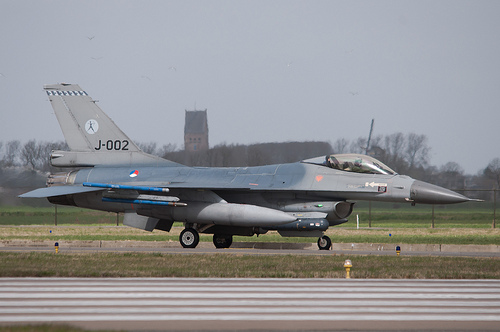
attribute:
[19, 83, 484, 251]
airplane — military, gray, blue, with one seat, small, silver, fighter, jet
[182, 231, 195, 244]
wheel — white, black, back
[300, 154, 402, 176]
cockpit — glass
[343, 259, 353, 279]
marking — yellow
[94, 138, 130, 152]
numbers — identification, identifying, black, j-002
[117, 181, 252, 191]
wing — partial, blue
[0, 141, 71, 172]
trees — without leaves, with no leaves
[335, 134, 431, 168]
trees — without leaves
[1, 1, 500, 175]
sky — overcast, gray, bright grey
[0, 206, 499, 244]
grass — green, in field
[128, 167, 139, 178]
decal — blue, white, red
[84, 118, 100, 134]
decal — with figure, circle, white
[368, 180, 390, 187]
arrow — pointing back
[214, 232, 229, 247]
wheel — black, back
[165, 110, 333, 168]
building — tall, narrow, in background, large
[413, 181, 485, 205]
nose — pointy, darker gray, sharp point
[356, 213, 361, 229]
pole — small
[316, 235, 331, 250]
front wheel — black, down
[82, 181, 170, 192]
rod — blue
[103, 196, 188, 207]
rod — blue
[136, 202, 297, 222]
cylinder — oval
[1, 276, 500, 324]
lines — grey, tan